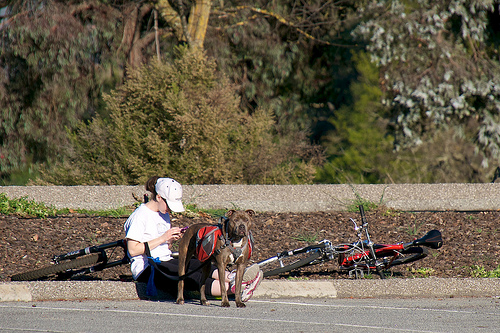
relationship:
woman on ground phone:
[126, 174, 187, 298] [168, 217, 182, 235]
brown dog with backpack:
[185, 204, 254, 306] [204, 220, 215, 244]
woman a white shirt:
[126, 174, 187, 298] [125, 216, 165, 240]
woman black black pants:
[126, 174, 187, 298] [134, 256, 213, 302]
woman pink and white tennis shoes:
[126, 174, 187, 298] [236, 254, 289, 329]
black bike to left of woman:
[20, 224, 132, 294] [126, 174, 187, 298]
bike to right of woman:
[260, 204, 444, 276] [126, 174, 187, 298]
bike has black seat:
[260, 204, 444, 276] [422, 168, 454, 277]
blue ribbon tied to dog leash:
[144, 246, 171, 312] [141, 246, 238, 287]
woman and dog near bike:
[113, 161, 282, 309] [230, 179, 435, 276]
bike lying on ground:
[230, 179, 435, 276] [281, 189, 334, 218]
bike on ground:
[260, 204, 444, 276] [281, 189, 334, 218]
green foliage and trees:
[311, 61, 378, 179] [184, 84, 482, 168]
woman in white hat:
[126, 174, 187, 298] [147, 181, 204, 224]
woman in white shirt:
[126, 174, 187, 298] [125, 216, 165, 240]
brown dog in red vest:
[185, 204, 254, 306] [194, 232, 222, 248]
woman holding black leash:
[126, 174, 187, 298] [138, 242, 236, 273]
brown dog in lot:
[177, 204, 255, 306] [128, 309, 329, 333]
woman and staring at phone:
[126, 174, 187, 298] [168, 204, 187, 237]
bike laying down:
[230, 179, 435, 276] [281, 232, 454, 261]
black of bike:
[255, 241, 323, 276] [230, 179, 435, 276]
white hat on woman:
[147, 181, 204, 224] [126, 174, 187, 298]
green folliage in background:
[313, 54, 398, 223] [20, 8, 497, 181]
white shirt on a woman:
[125, 216, 165, 240] [126, 174, 187, 298]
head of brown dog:
[230, 206, 259, 239] [185, 204, 254, 306]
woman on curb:
[126, 174, 187, 298] [65, 258, 398, 307]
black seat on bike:
[422, 168, 454, 277] [230, 179, 435, 276]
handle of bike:
[345, 182, 402, 331] [230, 179, 435, 276]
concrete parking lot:
[349, 302, 441, 328] [128, 309, 329, 333]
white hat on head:
[147, 181, 204, 224] [151, 158, 188, 233]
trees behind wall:
[184, 84, 482, 168] [75, 187, 421, 207]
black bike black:
[366, 233, 441, 289] [255, 241, 323, 276]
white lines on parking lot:
[314, 303, 497, 318] [10, 283, 472, 333]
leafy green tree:
[303, 13, 404, 196] [20, 8, 497, 181]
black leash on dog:
[138, 242, 236, 273] [185, 204, 254, 306]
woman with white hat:
[126, 174, 187, 298] [147, 181, 204, 224]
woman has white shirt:
[126, 174, 187, 298] [125, 216, 165, 240]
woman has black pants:
[126, 174, 187, 298] [142, 256, 251, 294]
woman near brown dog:
[126, 174, 187, 298] [185, 204, 254, 306]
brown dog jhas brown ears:
[177, 204, 255, 306] [223, 200, 259, 223]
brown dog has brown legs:
[177, 204, 255, 306] [167, 262, 267, 321]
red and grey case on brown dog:
[181, 201, 225, 272] [177, 204, 255, 306]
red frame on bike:
[338, 222, 406, 276] [230, 179, 435, 276]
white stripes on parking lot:
[140, 304, 370, 327] [10, 283, 472, 333]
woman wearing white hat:
[126, 174, 187, 298] [155, 176, 183, 211]